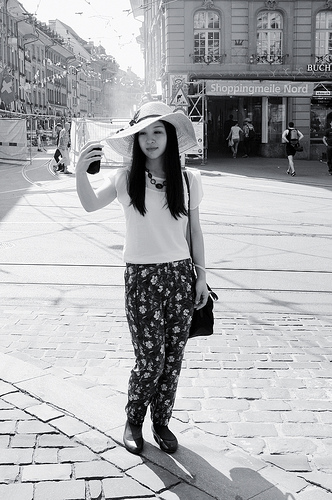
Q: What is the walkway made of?
A: Brick.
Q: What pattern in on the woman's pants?
A: Flowers.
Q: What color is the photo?
A: Black and white.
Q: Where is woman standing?
A: Brick plaza.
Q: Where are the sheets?
A: Hanging on lines.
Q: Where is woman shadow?
A: On bricks.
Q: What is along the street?
A: Row of buildings.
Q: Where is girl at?
A: Side of road.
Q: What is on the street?
A: Girls shadow.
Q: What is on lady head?
A: A hat.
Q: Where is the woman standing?
A: She is standing on a street corner.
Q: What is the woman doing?
A: The woman is taking a selfie.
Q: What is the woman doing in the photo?
A: She is a tourist in the city.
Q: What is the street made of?
A: The street is made of bricks.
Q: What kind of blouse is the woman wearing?
A: The woman is wearing a feminine white blouse.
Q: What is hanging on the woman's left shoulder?
A: A bag with a long strap is hanging on the woman's left shoulder.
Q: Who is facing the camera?
A: A woman.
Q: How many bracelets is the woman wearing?
A: One.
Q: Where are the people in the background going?
A: Into the store.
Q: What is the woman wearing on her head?
A: A hat.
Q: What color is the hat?
A: White.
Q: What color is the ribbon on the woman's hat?
A: Black.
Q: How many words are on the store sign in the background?
A: Two.